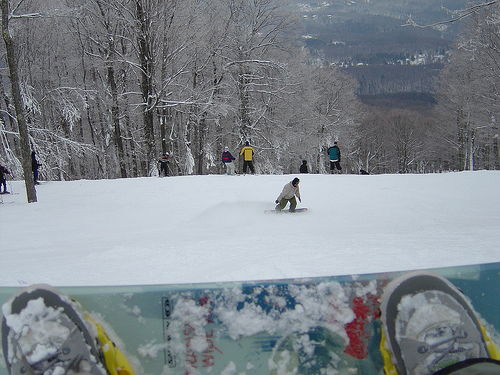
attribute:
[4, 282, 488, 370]
laces — grey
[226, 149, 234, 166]
jacket — red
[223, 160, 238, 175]
pants — white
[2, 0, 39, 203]
tree — leafless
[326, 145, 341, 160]
jacket — blue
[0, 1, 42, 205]
tree trunk — thin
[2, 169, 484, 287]
ski surface — snow covered